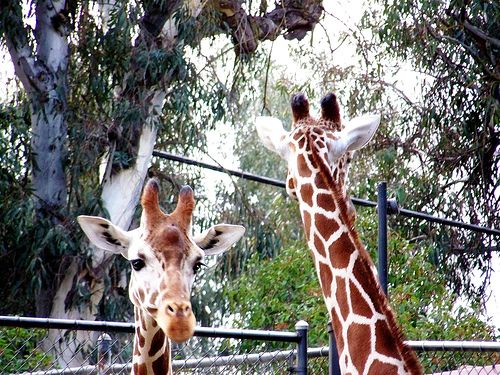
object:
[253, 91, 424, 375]
giraffe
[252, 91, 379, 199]
head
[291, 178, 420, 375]
neck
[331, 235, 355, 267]
spot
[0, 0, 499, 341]
sky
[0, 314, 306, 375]
fencing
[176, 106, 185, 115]
leaves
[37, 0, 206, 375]
trunk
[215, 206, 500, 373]
bush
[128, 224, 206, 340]
face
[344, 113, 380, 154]
ear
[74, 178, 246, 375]
giraffe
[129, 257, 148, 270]
eye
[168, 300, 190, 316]
nose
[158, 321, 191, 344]
mouth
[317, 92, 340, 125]
horn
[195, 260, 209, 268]
eyelashes